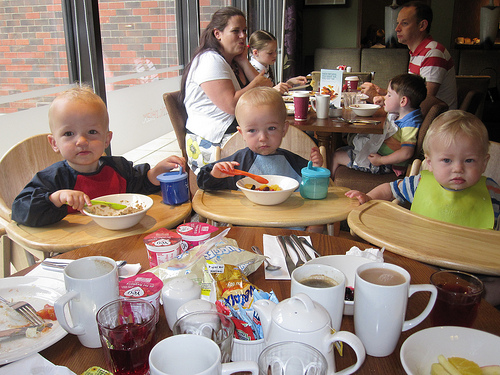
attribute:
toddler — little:
[341, 102, 498, 232]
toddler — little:
[11, 83, 194, 230]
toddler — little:
[191, 78, 329, 195]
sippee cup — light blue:
[293, 154, 333, 201]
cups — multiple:
[51, 239, 440, 373]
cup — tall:
[287, 257, 348, 339]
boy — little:
[195, 85, 330, 203]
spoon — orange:
[218, 166, 271, 186]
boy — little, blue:
[10, 153, 154, 229]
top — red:
[11, 153, 152, 232]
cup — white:
[352, 256, 438, 358]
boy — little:
[342, 103, 497, 228]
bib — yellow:
[405, 167, 496, 234]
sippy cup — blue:
[291, 151, 331, 200]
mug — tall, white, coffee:
[354, 254, 444, 359]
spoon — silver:
[245, 243, 288, 274]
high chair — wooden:
[194, 119, 364, 227]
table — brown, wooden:
[267, 55, 411, 146]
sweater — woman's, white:
[177, 45, 248, 147]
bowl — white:
[346, 100, 385, 120]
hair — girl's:
[246, 26, 278, 49]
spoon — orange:
[221, 159, 279, 190]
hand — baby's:
[214, 154, 244, 187]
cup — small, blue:
[294, 155, 341, 210]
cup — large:
[350, 255, 437, 371]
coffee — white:
[364, 264, 399, 285]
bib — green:
[404, 165, 497, 240]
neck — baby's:
[416, 174, 487, 203]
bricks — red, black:
[123, 19, 155, 57]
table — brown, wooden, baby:
[336, 196, 498, 285]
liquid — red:
[106, 332, 143, 367]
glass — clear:
[92, 294, 161, 371]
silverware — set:
[268, 224, 328, 277]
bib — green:
[401, 171, 499, 232]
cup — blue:
[295, 163, 345, 204]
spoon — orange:
[223, 162, 269, 187]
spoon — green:
[81, 188, 133, 211]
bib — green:
[406, 169, 498, 244]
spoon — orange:
[215, 161, 266, 187]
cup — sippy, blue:
[161, 158, 203, 209]